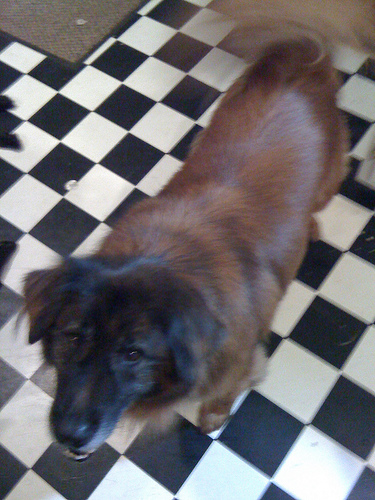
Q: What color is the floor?
A: Black and white.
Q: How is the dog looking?
A: Up.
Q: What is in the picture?
A: A dog.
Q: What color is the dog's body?
A: Brown.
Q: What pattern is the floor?
A: Checked.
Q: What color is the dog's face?
A: Black.